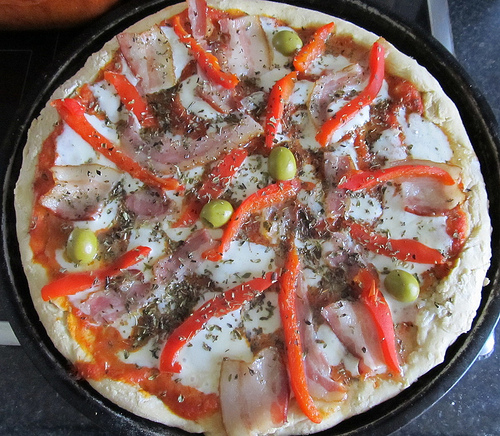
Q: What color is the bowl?
A: Black.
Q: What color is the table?
A: Blue.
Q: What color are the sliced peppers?
A: Red.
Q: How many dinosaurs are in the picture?
A: Zero.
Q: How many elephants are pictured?
A: Zero.